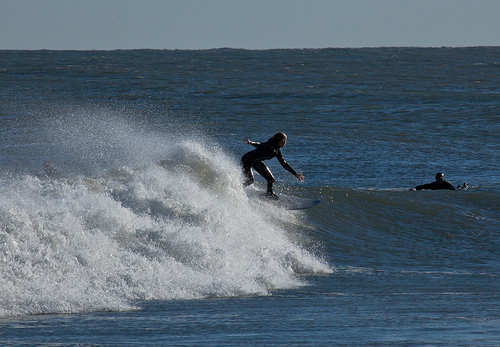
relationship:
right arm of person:
[243, 136, 268, 148] [237, 130, 307, 200]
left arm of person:
[244, 136, 260, 146] [236, 128, 306, 205]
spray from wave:
[19, 106, 167, 180] [84, 143, 296, 303]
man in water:
[409, 172, 456, 191] [0, 48, 499, 347]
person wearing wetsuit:
[241, 131, 305, 200] [222, 133, 309, 199]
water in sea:
[0, 48, 499, 347] [2, 50, 499, 342]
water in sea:
[0, 48, 499, 347] [48, 27, 426, 277]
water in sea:
[0, 48, 499, 347] [117, 75, 370, 269]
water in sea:
[61, 64, 216, 176] [59, 71, 434, 297]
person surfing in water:
[241, 131, 305, 200] [14, 59, 482, 339]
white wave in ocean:
[1, 139, 331, 315] [0, 45, 499, 345]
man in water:
[410, 166, 467, 196] [0, 48, 499, 347]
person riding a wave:
[241, 131, 305, 200] [323, 187, 399, 267]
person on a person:
[243, 126, 305, 206] [403, 171, 474, 197]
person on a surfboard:
[243, 126, 305, 206] [243, 179, 326, 211]